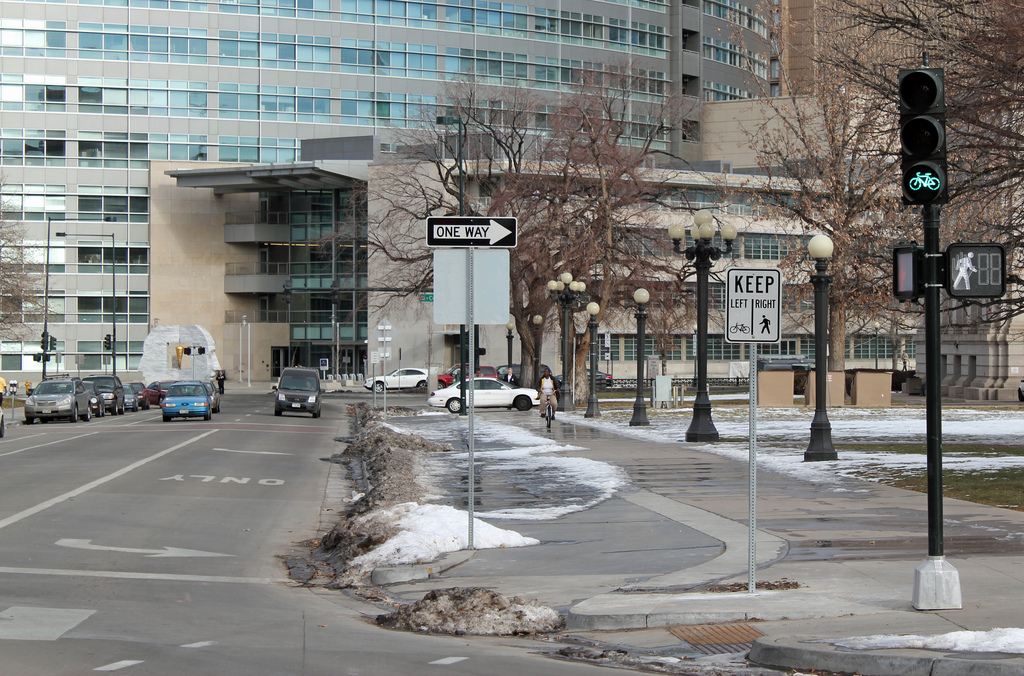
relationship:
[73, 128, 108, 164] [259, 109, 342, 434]
window on building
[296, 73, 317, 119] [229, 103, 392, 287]
window on building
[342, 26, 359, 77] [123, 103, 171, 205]
window on building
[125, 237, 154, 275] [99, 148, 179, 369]
window on building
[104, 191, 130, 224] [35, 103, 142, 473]
window on building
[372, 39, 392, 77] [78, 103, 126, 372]
window on building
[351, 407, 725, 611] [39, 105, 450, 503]
sidewalk and street in front of city building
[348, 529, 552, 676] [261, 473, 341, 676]
snow between street and sidewalk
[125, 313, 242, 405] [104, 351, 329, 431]
statues of two profiles in back of parked cars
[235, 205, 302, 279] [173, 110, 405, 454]
roofed and terraced entryway into building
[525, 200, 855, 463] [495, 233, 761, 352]
black poles has light with globes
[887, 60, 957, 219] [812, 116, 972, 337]
traffic signal showing lit bicycle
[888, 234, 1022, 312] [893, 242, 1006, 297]
traffic signal showing traffic signal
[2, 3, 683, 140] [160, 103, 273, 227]
window panes on curved building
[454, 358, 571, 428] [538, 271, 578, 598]
bicyclist riding in front of car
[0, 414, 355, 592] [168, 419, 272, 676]
white lines arrow and print on street surface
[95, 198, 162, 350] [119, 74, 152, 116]
building has a window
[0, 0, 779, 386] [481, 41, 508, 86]
building has a window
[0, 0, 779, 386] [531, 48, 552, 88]
building has a window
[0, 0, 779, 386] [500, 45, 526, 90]
building has a window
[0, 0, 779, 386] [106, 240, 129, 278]
building has a window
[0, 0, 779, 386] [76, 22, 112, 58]
building has a window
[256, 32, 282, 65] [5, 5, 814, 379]
window on building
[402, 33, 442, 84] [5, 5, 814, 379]
window on building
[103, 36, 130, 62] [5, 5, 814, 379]
window on building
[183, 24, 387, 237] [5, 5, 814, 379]
window on building